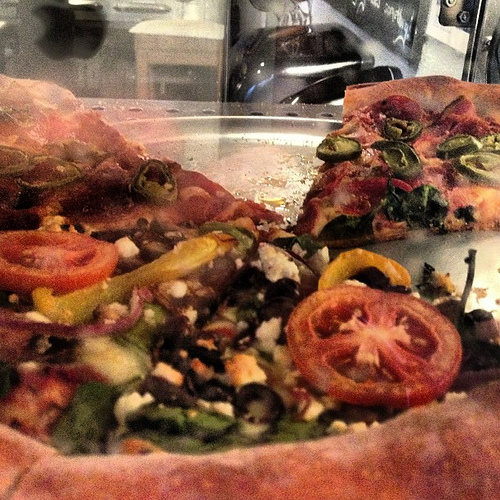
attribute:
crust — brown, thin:
[343, 71, 499, 126]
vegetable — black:
[234, 380, 283, 425]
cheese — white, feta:
[256, 241, 298, 284]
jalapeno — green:
[131, 158, 178, 202]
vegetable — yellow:
[315, 246, 412, 291]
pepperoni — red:
[378, 95, 423, 121]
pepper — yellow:
[30, 233, 221, 326]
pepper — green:
[13, 153, 81, 191]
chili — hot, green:
[315, 135, 364, 162]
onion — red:
[0, 284, 151, 334]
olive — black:
[184, 365, 235, 401]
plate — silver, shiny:
[77, 96, 500, 332]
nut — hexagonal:
[456, 9, 472, 25]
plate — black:
[436, 0, 476, 27]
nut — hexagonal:
[444, 0, 456, 8]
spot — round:
[164, 108, 180, 116]